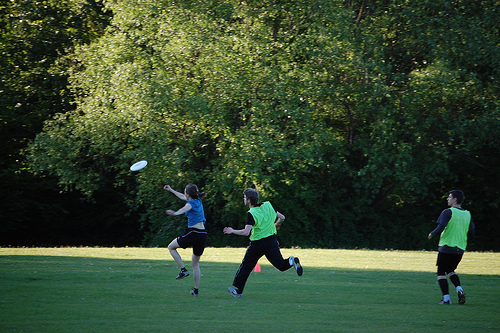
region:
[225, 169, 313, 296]
man chasing after a frisbee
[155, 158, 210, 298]
man in blue chasing after a frisbee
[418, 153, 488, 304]
man chasing after a frisbee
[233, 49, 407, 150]
trees in the distance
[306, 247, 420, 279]
sun reflecting on the grass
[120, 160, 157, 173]
white frisbee in the air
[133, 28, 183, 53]
green leaves on top of the trees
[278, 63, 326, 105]
green leaves on top of the trees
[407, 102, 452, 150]
green leaves on top of the trees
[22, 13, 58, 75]
green leaves on top of the trees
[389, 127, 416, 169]
green leaves on top of the trees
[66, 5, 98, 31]
green leaves on top of the trees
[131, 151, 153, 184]
frisbee in the air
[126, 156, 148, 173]
white frisbee flying through the air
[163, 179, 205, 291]
person in blue running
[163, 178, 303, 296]
person in green near person in blue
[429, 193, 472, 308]
person in green in the back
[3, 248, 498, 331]
green field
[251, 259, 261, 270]
orange cone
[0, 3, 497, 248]
trees are in the background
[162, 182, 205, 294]
person in blue is wearing black shorts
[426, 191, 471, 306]
person in green wearing black shorts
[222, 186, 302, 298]
person in green wearing black pants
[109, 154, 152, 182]
A white frisbee in the air.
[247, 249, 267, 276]
An orange cone on the ground.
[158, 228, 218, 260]
The person is wearing black shorts.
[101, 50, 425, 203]
The trees are big and green.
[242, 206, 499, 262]
Two people wearing green shirts.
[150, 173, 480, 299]
People are running after the frisbee.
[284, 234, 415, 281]
Reflection of the sun in the grass.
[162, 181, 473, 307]
Three people playing frisbee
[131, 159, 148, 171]
A white frisbee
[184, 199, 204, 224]
A person wearing a blue shirt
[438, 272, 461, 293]
A person with tall socks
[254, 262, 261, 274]
An oragne cone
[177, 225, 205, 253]
A man with dark shorts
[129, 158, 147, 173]
A frisbee in the air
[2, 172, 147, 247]
Shadows under some trees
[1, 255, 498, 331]
A shadow acroos the grass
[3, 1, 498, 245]
green leaves on trees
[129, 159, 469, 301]
three people playing frisbee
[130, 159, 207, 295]
girl reaching for airborne frisbee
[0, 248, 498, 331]
field of green grass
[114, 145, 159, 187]
a white frisbee flying in the air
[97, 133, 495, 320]
a group of three people playing frisbee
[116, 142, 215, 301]
a person chasing after a frisbee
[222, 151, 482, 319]
two people on a team playing a sport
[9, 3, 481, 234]
several large green trees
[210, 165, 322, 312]
a person running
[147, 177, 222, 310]
a person wearing shorts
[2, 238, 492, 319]
a grassy sports field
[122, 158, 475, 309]
three people playing Frisbee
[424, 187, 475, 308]
one man standing in a field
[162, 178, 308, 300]
one man chasing another man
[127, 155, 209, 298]
man trying to catch a Frisbee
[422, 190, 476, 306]
man wearing a green vest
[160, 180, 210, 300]
man wearing a blue shirt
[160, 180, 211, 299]
man with his knee raised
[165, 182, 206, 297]
Man in a blue shirt and black shorts jumping.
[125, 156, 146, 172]
White disk flying in the air.